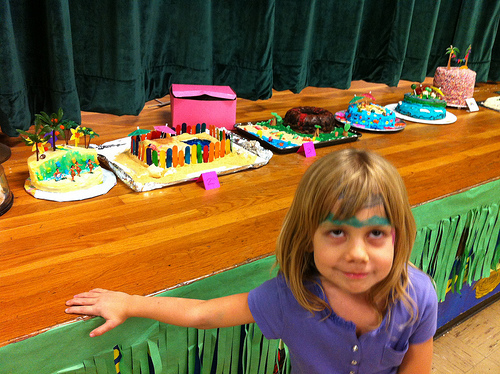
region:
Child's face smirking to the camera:
[279, 145, 425, 295]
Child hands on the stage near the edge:
[60, 284, 139, 339]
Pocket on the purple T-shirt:
[381, 336, 413, 368]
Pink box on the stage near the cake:
[164, 80, 241, 132]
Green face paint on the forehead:
[316, 208, 395, 228]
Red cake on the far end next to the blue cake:
[431, 44, 483, 111]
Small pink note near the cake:
[196, 168, 224, 190]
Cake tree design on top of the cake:
[21, 105, 100, 163]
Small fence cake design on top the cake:
[119, 123, 238, 170]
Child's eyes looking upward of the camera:
[322, 224, 390, 246]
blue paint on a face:
[325, 208, 385, 230]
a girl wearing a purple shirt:
[248, 141, 447, 372]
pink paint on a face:
[389, 225, 399, 242]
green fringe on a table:
[430, 190, 497, 284]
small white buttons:
[344, 340, 362, 372]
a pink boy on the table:
[162, 76, 236, 125]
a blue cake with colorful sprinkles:
[346, 93, 396, 132]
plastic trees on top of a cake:
[15, 115, 97, 151]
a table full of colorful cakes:
[20, 43, 498, 196]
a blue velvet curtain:
[9, 4, 489, 91]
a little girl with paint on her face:
[300, 158, 415, 291]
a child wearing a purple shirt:
[228, 257, 463, 372]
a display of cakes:
[0, 36, 479, 226]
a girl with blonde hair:
[275, 143, 415, 309]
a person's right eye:
[320, 225, 345, 240]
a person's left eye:
[360, 225, 380, 240]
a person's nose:
[343, 238, 368, 263]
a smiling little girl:
[297, 191, 404, 306]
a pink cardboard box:
[162, 78, 243, 130]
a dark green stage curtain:
[21, 4, 471, 119]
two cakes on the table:
[337, 79, 450, 136]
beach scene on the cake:
[12, 108, 112, 205]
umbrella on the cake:
[130, 123, 150, 139]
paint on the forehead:
[320, 189, 397, 226]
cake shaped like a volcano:
[279, 100, 339, 134]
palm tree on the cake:
[439, 40, 459, 70]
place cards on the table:
[194, 166, 224, 195]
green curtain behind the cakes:
[47, 18, 137, 99]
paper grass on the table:
[437, 195, 492, 275]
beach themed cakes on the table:
[242, 44, 484, 153]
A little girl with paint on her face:
[294, 144, 419, 301]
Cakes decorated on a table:
[61, 34, 479, 196]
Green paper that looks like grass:
[442, 203, 486, 290]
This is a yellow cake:
[32, 117, 121, 196]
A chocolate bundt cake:
[283, 94, 346, 146]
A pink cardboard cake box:
[174, 77, 243, 123]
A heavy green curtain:
[201, 14, 383, 66]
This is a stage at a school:
[1, 87, 218, 281]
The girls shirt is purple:
[278, 283, 406, 366]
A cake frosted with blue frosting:
[351, 92, 396, 130]